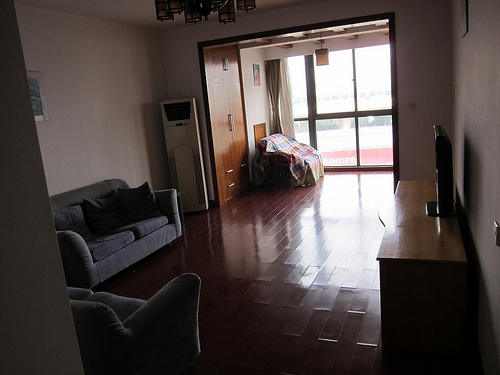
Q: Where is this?
A: This is at the office.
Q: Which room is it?
A: It is an office.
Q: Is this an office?
A: Yes, it is an office.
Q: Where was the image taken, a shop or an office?
A: It was taken at an office.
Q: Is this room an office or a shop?
A: It is an office.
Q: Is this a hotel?
A: No, it is an office.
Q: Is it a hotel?
A: No, it is an office.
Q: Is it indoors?
A: Yes, it is indoors.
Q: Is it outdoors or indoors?
A: It is indoors.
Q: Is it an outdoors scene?
A: No, it is indoors.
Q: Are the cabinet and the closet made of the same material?
A: Yes, both the cabinet and the closet are made of wood.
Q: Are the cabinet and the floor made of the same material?
A: Yes, both the cabinet and the floor are made of wood.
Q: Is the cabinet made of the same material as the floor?
A: Yes, both the cabinet and the floor are made of wood.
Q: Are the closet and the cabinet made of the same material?
A: Yes, both the closet and the cabinet are made of wood.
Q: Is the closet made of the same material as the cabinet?
A: Yes, both the closet and the cabinet are made of wood.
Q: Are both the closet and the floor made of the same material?
A: Yes, both the closet and the floor are made of wood.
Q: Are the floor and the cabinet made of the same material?
A: Yes, both the floor and the cabinet are made of wood.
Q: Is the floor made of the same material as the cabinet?
A: Yes, both the floor and the cabinet are made of wood.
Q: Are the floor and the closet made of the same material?
A: Yes, both the floor and the closet are made of wood.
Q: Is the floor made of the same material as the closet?
A: Yes, both the floor and the closet are made of wood.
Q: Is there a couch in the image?
A: Yes, there is a couch.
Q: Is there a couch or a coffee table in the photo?
A: Yes, there is a couch.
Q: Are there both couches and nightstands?
A: No, there is a couch but no nightstands.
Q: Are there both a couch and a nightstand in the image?
A: No, there is a couch but no nightstands.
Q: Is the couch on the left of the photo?
A: Yes, the couch is on the left of the image.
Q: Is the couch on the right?
A: No, the couch is on the left of the image.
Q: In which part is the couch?
A: The couch is on the left of the image.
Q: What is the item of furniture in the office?
A: The piece of furniture is a couch.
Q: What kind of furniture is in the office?
A: The piece of furniture is a couch.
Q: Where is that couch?
A: The couch is in the office.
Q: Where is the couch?
A: The couch is in the office.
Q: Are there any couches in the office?
A: Yes, there is a couch in the office.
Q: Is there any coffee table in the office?
A: No, there is a couch in the office.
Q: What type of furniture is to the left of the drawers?
A: The piece of furniture is a couch.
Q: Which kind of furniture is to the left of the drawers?
A: The piece of furniture is a couch.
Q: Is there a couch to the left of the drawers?
A: Yes, there is a couch to the left of the drawers.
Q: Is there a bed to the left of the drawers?
A: No, there is a couch to the left of the drawers.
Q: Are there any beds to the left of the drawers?
A: No, there is a couch to the left of the drawers.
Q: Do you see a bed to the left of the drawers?
A: No, there is a couch to the left of the drawers.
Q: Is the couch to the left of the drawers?
A: Yes, the couch is to the left of the drawers.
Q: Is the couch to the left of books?
A: No, the couch is to the left of the drawers.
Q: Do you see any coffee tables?
A: No, there are no coffee tables.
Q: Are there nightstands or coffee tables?
A: No, there are no coffee tables or nightstands.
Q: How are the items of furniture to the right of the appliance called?
A: The pieces of furniture are drawers.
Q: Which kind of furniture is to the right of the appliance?
A: The pieces of furniture are drawers.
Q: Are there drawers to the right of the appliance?
A: Yes, there are drawers to the right of the appliance.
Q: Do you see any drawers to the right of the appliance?
A: Yes, there are drawers to the right of the appliance.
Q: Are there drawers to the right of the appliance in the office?
A: Yes, there are drawers to the right of the appliance.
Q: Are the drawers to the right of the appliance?
A: Yes, the drawers are to the right of the appliance.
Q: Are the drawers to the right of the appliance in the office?
A: Yes, the drawers are to the right of the appliance.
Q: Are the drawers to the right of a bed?
A: No, the drawers are to the right of the appliance.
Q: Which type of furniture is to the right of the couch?
A: The pieces of furniture are drawers.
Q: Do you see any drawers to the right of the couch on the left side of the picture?
A: Yes, there are drawers to the right of the couch.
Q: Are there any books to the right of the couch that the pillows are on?
A: No, there are drawers to the right of the couch.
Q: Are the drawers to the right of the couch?
A: Yes, the drawers are to the right of the couch.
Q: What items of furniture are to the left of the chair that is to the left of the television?
A: The pieces of furniture are drawers.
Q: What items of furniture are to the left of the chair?
A: The pieces of furniture are drawers.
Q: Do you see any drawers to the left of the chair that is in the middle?
A: Yes, there are drawers to the left of the chair.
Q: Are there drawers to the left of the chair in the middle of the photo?
A: Yes, there are drawers to the left of the chair.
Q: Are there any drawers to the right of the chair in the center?
A: No, the drawers are to the left of the chair.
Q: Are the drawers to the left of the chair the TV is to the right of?
A: Yes, the drawers are to the left of the chair.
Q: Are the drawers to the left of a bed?
A: No, the drawers are to the left of the chair.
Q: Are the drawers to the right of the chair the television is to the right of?
A: No, the drawers are to the left of the chair.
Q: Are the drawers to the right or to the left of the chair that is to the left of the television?
A: The drawers are to the left of the chair.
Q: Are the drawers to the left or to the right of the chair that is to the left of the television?
A: The drawers are to the left of the chair.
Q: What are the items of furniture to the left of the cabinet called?
A: The pieces of furniture are drawers.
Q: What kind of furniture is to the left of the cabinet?
A: The pieces of furniture are drawers.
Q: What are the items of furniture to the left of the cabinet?
A: The pieces of furniture are drawers.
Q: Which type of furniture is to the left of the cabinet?
A: The pieces of furniture are drawers.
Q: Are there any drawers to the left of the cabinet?
A: Yes, there are drawers to the left of the cabinet.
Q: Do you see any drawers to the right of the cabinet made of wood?
A: No, the drawers are to the left of the cabinet.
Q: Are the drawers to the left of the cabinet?
A: Yes, the drawers are to the left of the cabinet.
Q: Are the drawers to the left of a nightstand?
A: No, the drawers are to the left of the cabinet.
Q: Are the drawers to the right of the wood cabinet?
A: No, the drawers are to the left of the cabinet.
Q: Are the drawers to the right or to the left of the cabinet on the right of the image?
A: The drawers are to the left of the cabinet.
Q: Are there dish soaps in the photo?
A: No, there are no dish soaps.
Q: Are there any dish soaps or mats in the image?
A: No, there are no dish soaps or mats.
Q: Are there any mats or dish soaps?
A: No, there are no dish soaps or mats.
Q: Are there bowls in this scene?
A: No, there are no bowls.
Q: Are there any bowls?
A: No, there are no bowls.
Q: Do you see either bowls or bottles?
A: No, there are no bowls or bottles.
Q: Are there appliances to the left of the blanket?
A: Yes, there is an appliance to the left of the blanket.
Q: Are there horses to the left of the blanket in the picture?
A: No, there is an appliance to the left of the blanket.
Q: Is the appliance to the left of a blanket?
A: Yes, the appliance is to the left of a blanket.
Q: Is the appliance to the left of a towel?
A: No, the appliance is to the left of a blanket.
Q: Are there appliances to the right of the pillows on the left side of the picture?
A: Yes, there is an appliance to the right of the pillows.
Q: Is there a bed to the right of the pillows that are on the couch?
A: No, there is an appliance to the right of the pillows.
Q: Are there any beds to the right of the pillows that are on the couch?
A: No, there is an appliance to the right of the pillows.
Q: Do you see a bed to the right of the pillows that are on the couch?
A: No, there is an appliance to the right of the pillows.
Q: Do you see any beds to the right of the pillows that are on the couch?
A: No, there is an appliance to the right of the pillows.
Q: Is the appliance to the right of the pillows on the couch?
A: Yes, the appliance is to the right of the pillows.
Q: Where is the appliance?
A: The appliance is in the office.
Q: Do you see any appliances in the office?
A: Yes, there is an appliance in the office.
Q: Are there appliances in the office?
A: Yes, there is an appliance in the office.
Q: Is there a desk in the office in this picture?
A: No, there is an appliance in the office.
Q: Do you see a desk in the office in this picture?
A: No, there is an appliance in the office.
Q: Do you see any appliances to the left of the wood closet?
A: Yes, there is an appliance to the left of the closet.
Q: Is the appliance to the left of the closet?
A: Yes, the appliance is to the left of the closet.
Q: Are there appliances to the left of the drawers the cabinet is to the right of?
A: Yes, there is an appliance to the left of the drawers.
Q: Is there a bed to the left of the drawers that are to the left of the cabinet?
A: No, there is an appliance to the left of the drawers.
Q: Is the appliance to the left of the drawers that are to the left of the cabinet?
A: Yes, the appliance is to the left of the drawers.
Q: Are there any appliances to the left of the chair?
A: Yes, there is an appliance to the left of the chair.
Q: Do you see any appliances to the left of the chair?
A: Yes, there is an appliance to the left of the chair.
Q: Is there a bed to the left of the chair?
A: No, there is an appliance to the left of the chair.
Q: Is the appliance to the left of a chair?
A: Yes, the appliance is to the left of a chair.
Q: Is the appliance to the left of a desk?
A: No, the appliance is to the left of a chair.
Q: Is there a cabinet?
A: Yes, there is a cabinet.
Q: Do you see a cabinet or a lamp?
A: Yes, there is a cabinet.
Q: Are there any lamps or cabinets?
A: Yes, there is a cabinet.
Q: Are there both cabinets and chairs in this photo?
A: Yes, there are both a cabinet and a chair.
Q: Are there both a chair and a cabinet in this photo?
A: Yes, there are both a cabinet and a chair.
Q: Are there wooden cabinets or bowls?
A: Yes, there is a wood cabinet.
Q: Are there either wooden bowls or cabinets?
A: Yes, there is a wood cabinet.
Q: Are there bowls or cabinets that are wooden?
A: Yes, the cabinet is wooden.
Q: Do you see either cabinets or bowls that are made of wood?
A: Yes, the cabinet is made of wood.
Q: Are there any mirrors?
A: No, there are no mirrors.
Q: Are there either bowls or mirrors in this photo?
A: No, there are no mirrors or bowls.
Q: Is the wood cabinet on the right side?
A: Yes, the cabinet is on the right of the image.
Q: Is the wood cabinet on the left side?
A: No, the cabinet is on the right of the image.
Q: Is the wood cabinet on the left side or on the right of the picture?
A: The cabinet is on the right of the image.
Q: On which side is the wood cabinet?
A: The cabinet is on the right of the image.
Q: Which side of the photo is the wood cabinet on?
A: The cabinet is on the right of the image.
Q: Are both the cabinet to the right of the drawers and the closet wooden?
A: Yes, both the cabinet and the closet are wooden.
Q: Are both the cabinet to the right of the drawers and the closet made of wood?
A: Yes, both the cabinet and the closet are made of wood.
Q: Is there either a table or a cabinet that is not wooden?
A: No, there is a cabinet but it is wooden.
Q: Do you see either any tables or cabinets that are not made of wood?
A: No, there is a cabinet but it is made of wood.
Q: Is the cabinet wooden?
A: Yes, the cabinet is wooden.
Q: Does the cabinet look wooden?
A: Yes, the cabinet is wooden.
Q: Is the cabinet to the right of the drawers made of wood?
A: Yes, the cabinet is made of wood.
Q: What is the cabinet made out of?
A: The cabinet is made of wood.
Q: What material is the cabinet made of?
A: The cabinet is made of wood.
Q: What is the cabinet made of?
A: The cabinet is made of wood.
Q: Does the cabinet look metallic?
A: No, the cabinet is wooden.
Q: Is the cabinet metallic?
A: No, the cabinet is wooden.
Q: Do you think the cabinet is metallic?
A: No, the cabinet is wooden.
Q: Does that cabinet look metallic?
A: No, the cabinet is wooden.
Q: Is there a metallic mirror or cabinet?
A: No, there is a cabinet but it is wooden.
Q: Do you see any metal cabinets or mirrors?
A: No, there is a cabinet but it is wooden.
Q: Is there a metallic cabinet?
A: No, there is a cabinet but it is wooden.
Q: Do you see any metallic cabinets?
A: No, there is a cabinet but it is wooden.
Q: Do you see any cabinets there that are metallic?
A: No, there is a cabinet but it is wooden.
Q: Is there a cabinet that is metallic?
A: No, there is a cabinet but it is wooden.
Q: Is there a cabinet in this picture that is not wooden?
A: No, there is a cabinet but it is wooden.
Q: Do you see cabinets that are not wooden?
A: No, there is a cabinet but it is wooden.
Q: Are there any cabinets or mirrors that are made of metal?
A: No, there is a cabinet but it is made of wood.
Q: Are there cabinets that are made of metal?
A: No, there is a cabinet but it is made of wood.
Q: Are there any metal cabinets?
A: No, there is a cabinet but it is made of wood.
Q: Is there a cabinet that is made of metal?
A: No, there is a cabinet but it is made of wood.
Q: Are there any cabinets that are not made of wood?
A: No, there is a cabinet but it is made of wood.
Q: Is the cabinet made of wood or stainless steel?
A: The cabinet is made of wood.